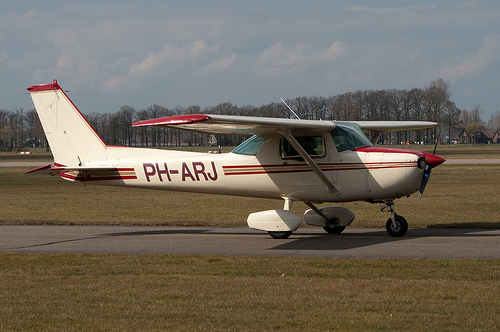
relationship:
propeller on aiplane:
[406, 137, 450, 189] [27, 68, 456, 249]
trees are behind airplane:
[0, 81, 490, 150] [23, 74, 446, 239]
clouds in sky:
[136, 40, 218, 77] [52, 1, 149, 21]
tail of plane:
[18, 71, 146, 211] [25, 48, 444, 278]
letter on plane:
[135, 158, 159, 194] [35, 80, 427, 280]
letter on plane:
[155, 159, 170, 179] [12, 70, 424, 257]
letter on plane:
[179, 164, 193, 185] [12, 57, 436, 259]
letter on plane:
[191, 155, 207, 182] [36, 81, 450, 267]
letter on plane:
[210, 158, 223, 184] [7, 58, 458, 268]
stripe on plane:
[232, 159, 278, 178] [32, 67, 450, 240]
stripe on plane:
[100, 166, 142, 176] [25, 48, 444, 278]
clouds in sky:
[136, 40, 218, 77] [169, 1, 346, 33]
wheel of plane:
[377, 210, 415, 245] [12, 57, 436, 259]